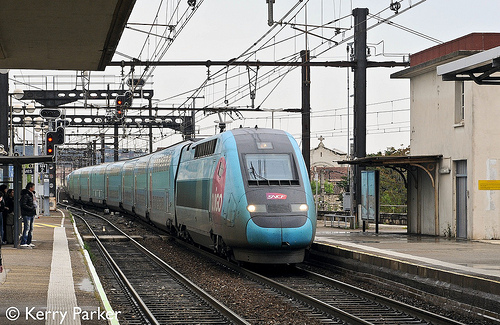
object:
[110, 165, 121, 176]
window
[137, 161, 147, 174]
window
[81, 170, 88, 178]
window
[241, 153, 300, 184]
window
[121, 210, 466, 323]
track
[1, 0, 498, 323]
train depot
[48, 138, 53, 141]
light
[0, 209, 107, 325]
loading platform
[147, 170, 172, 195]
window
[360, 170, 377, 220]
sign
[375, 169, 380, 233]
pole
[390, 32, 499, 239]
building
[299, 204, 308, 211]
light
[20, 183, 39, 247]
man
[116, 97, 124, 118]
light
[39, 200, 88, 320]
line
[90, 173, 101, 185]
window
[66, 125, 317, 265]
train